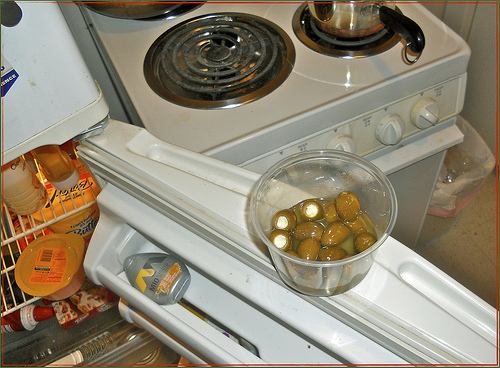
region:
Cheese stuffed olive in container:
[297, 195, 323, 220]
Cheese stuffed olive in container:
[265, 207, 300, 229]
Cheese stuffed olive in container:
[270, 228, 290, 248]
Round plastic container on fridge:
[252, 149, 396, 295]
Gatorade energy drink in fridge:
[118, 248, 193, 308]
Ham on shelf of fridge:
[10, 233, 89, 301]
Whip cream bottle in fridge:
[0, 300, 59, 335]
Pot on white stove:
[302, 0, 426, 67]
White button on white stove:
[412, 98, 441, 132]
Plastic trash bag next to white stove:
[426, 106, 495, 223]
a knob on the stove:
[410, 98, 442, 131]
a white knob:
[411, 95, 436, 132]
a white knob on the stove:
[408, 99, 440, 128]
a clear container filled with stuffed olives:
[254, 149, 399, 296]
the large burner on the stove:
[151, 15, 291, 105]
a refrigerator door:
[70, 125, 497, 365]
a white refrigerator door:
[86, 135, 481, 367]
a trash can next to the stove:
[418, 105, 498, 243]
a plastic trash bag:
[428, 110, 487, 225]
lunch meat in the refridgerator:
[12, 232, 85, 301]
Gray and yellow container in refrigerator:
[128, 250, 188, 300]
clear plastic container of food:
[245, 140, 397, 286]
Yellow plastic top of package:
[7, 234, 84, 299]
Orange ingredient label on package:
[31, 245, 67, 286]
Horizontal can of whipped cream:
[6, 304, 51, 332]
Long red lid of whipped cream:
[36, 304, 51, 319]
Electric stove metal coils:
[142, 15, 292, 98]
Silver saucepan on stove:
[307, 0, 433, 50]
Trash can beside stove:
[427, 103, 492, 224]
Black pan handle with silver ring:
[380, 3, 423, 65]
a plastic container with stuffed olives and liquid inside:
[245, 146, 397, 298]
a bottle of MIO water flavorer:
[122, 249, 189, 305]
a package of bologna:
[12, 230, 88, 304]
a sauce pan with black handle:
[300, 1, 428, 71]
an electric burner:
[142, 8, 297, 113]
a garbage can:
[427, 108, 494, 220]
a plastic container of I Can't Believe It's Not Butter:
[36, 162, 101, 239]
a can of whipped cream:
[0, 300, 55, 332]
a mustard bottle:
[29, 148, 81, 193]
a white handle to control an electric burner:
[406, 93, 444, 129]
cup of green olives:
[256, 155, 384, 282]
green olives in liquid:
[294, 200, 339, 247]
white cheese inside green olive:
[302, 193, 325, 221]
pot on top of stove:
[306, 0, 420, 68]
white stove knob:
[412, 97, 454, 126]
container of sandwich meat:
[25, 235, 78, 301]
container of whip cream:
[6, 306, 58, 329]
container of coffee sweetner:
[0, 171, 52, 201]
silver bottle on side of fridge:
[102, 253, 204, 315]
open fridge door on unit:
[82, 152, 458, 364]